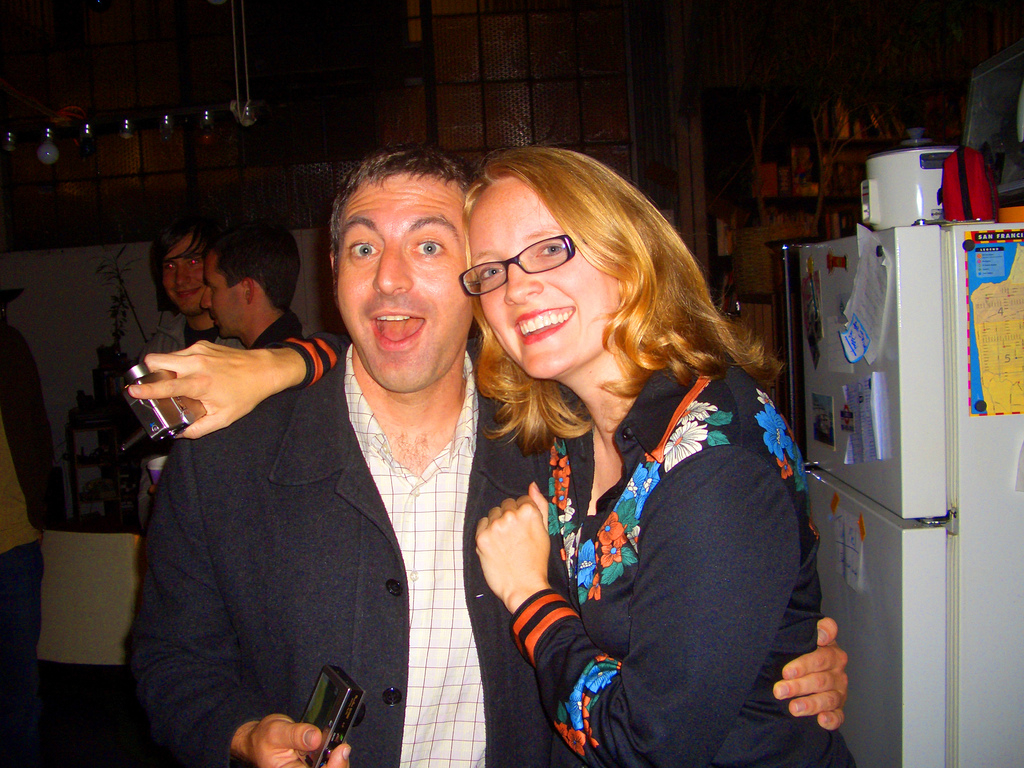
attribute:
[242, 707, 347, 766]
hand — man's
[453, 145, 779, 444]
hair — red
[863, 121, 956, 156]
lid — gray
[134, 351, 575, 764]
jacket — gray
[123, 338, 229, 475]
camera — pink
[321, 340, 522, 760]
shirt — square patterned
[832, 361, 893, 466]
paper — white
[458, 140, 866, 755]
woman — smiling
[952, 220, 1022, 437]
magnet — blue, yellow